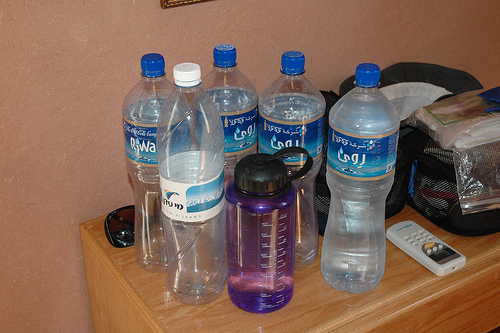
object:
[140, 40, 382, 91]
bottle caps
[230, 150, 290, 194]
lid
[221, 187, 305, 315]
tumbler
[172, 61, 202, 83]
cap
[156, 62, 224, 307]
water bottle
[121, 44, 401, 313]
bottles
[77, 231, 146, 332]
counter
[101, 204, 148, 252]
sunglasses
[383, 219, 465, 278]
remote control